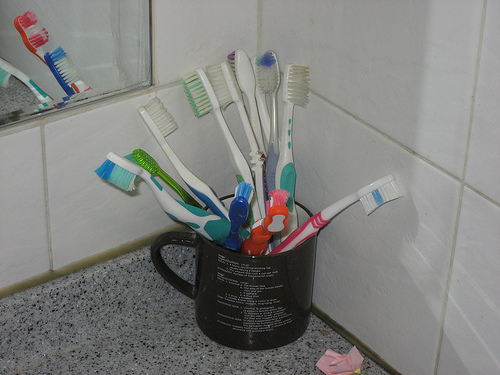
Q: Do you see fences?
A: No, there are no fences.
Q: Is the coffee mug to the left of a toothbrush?
A: Yes, the coffee mug is to the left of a toothbrush.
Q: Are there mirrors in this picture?
A: Yes, there is a mirror.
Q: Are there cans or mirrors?
A: Yes, there is a mirror.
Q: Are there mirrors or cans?
A: Yes, there is a mirror.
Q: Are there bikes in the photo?
A: No, there are no bikes.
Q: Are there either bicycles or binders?
A: No, there are no bicycles or binders.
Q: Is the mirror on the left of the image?
A: Yes, the mirror is on the left of the image.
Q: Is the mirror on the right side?
A: No, the mirror is on the left of the image.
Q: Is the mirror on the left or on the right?
A: The mirror is on the left of the image.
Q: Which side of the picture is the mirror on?
A: The mirror is on the left of the image.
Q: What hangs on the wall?
A: The mirror hangs on the wall.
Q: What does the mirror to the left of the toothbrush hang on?
A: The mirror hangs on the wall.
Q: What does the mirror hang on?
A: The mirror hangs on the wall.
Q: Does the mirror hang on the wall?
A: Yes, the mirror hangs on the wall.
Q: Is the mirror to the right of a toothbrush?
A: No, the mirror is to the left of a toothbrush.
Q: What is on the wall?
A: The mirror is on the wall.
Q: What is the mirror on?
A: The mirror is on the wall.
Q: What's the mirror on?
A: The mirror is on the wall.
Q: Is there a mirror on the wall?
A: Yes, there is a mirror on the wall.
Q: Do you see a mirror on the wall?
A: Yes, there is a mirror on the wall.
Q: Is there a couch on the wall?
A: No, there is a mirror on the wall.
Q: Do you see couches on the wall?
A: No, there is a mirror on the wall.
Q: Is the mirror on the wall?
A: Yes, the mirror is on the wall.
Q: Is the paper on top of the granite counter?
A: Yes, the paper is on top of the counter.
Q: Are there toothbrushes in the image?
A: Yes, there is a toothbrush.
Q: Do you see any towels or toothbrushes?
A: Yes, there is a toothbrush.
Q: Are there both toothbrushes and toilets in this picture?
A: No, there is a toothbrush but no toilets.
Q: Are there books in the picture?
A: No, there are no books.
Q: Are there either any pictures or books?
A: No, there are no books or pictures.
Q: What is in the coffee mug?
A: The toothbrush is in the coffee mug.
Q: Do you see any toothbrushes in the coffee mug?
A: Yes, there is a toothbrush in the coffee mug.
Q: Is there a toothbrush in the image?
A: Yes, there is a toothbrush.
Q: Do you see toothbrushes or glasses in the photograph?
A: Yes, there is a toothbrush.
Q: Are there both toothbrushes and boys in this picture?
A: No, there is a toothbrush but no boys.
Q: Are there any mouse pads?
A: No, there are no mouse pads.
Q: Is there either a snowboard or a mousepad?
A: No, there are no mouse pads or snowboards.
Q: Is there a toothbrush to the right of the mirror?
A: Yes, there is a toothbrush to the right of the mirror.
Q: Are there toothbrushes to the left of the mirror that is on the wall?
A: No, the toothbrush is to the right of the mirror.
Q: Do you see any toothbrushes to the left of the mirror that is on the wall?
A: No, the toothbrush is to the right of the mirror.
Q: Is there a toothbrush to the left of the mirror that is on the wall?
A: No, the toothbrush is to the right of the mirror.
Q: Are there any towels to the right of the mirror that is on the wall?
A: No, there is a toothbrush to the right of the mirror.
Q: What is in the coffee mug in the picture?
A: The toothbrush is in the coffee mug.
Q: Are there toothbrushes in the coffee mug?
A: Yes, there is a toothbrush in the coffee mug.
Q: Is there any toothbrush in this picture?
A: Yes, there is a toothbrush.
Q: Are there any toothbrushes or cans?
A: Yes, there is a toothbrush.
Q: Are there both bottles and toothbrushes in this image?
A: No, there is a toothbrush but no bottles.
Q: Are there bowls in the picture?
A: No, there are no bowls.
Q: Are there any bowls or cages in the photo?
A: No, there are no bowls or cages.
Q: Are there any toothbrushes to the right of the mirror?
A: Yes, there is a toothbrush to the right of the mirror.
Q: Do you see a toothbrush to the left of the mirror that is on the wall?
A: No, the toothbrush is to the right of the mirror.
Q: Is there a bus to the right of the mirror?
A: No, there is a toothbrush to the right of the mirror.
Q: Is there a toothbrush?
A: Yes, there is a toothbrush.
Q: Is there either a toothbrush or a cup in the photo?
A: Yes, there is a toothbrush.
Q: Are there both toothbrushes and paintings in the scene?
A: No, there is a toothbrush but no paintings.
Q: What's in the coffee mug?
A: The toothbrush is in the coffee mug.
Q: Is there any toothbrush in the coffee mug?
A: Yes, there is a toothbrush in the coffee mug.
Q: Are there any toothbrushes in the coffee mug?
A: Yes, there is a toothbrush in the coffee mug.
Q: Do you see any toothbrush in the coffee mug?
A: Yes, there is a toothbrush in the coffee mug.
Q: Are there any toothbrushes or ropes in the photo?
A: Yes, there is a toothbrush.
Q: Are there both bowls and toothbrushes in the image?
A: No, there is a toothbrush but no bowls.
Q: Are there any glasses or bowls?
A: No, there are no bowls or glasses.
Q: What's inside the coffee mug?
A: The toothbrush is inside the coffee mug.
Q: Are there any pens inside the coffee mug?
A: No, there is a toothbrush inside the coffee mug.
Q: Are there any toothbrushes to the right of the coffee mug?
A: Yes, there is a toothbrush to the right of the coffee mug.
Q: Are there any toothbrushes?
A: Yes, there is a toothbrush.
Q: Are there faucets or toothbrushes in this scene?
A: Yes, there is a toothbrush.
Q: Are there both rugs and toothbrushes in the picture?
A: No, there is a toothbrush but no rugs.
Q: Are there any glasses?
A: No, there are no glasses.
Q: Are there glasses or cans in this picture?
A: No, there are no glasses or cans.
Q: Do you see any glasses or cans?
A: No, there are no glasses or cans.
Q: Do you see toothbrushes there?
A: Yes, there is a toothbrush.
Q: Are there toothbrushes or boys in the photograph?
A: Yes, there is a toothbrush.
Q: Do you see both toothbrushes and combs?
A: No, there is a toothbrush but no combs.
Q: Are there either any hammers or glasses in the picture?
A: No, there are no glasses or hammers.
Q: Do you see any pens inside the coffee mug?
A: No, there is a toothbrush inside the coffee mug.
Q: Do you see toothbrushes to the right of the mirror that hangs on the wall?
A: Yes, there is a toothbrush to the right of the mirror.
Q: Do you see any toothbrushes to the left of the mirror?
A: No, the toothbrush is to the right of the mirror.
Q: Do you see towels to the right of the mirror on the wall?
A: No, there is a toothbrush to the right of the mirror.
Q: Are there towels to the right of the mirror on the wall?
A: No, there is a toothbrush to the right of the mirror.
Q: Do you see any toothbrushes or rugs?
A: Yes, there is a toothbrush.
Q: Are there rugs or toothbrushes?
A: Yes, there is a toothbrush.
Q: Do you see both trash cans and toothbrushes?
A: No, there is a toothbrush but no trash cans.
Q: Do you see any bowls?
A: No, there are no bowls.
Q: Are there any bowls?
A: No, there are no bowls.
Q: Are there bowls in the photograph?
A: No, there are no bowls.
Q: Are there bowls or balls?
A: No, there are no bowls or balls.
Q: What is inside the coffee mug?
A: The toothbrush is inside the coffee mug.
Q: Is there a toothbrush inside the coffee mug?
A: Yes, there is a toothbrush inside the coffee mug.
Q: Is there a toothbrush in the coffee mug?
A: Yes, there is a toothbrush in the coffee mug.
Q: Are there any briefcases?
A: No, there are no briefcases.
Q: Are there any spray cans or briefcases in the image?
A: No, there are no briefcases or spray cans.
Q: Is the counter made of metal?
A: No, the counter is made of granite.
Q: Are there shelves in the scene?
A: No, there are no shelves.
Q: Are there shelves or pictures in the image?
A: No, there are no shelves or pictures.